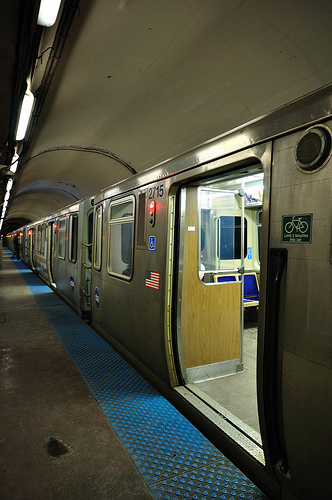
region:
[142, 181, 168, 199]
numbers on the side of the train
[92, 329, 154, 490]
blue metal divider of the boarding rail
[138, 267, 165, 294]
american flag on the side of the train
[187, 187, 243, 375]
wood paneled divider on the inside of the train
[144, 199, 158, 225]
boarding lights next to the door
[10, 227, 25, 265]
a man stepping onto the train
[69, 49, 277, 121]
white concrete cieling of the subway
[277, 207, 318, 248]
green and white sign showing a bicycle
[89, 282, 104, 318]
blue logo of the train company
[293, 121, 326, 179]
speaker on the side of the train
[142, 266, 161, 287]
an american flag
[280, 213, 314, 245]
green and white sign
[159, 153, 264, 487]
subway doors that are open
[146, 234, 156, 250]
white and blue handicap sign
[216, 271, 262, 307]
two blue seats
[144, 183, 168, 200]
number 2715 on side of subway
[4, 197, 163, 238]
red lights lit up along subway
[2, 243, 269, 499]
bumpy blue painted stripe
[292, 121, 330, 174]
a round speaker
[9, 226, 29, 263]
a person getting on the subway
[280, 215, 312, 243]
bike sign on subway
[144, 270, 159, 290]
US flag on subway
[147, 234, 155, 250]
Handicap stick on subway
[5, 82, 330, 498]
silver colored subway train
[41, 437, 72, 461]
small puddle on ground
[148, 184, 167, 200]
black subway train number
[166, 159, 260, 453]
open door on subway train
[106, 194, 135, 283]
window on subway train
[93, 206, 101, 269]
window on subway train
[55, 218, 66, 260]
window on subway train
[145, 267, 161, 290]
american flag sticker on the subway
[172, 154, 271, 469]
door entrance to the subway train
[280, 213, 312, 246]
bicycle sign on the side of the train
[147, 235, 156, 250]
handicapped sign on the side of the train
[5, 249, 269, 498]
blue textured stepping surface next to the subway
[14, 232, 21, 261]
man entering the subway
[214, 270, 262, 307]
blue seat on the subway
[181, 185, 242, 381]
wood wall partition inside the subway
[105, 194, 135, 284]
passenger window on the subway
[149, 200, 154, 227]
red lit light on the side of the train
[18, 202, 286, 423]
train doors are open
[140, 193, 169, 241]
red light on the wall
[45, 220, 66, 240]
red light on the wall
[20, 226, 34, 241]
red light on the wall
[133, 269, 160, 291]
American flag beside the door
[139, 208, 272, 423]
train door is open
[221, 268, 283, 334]
the seat is blue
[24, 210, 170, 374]
the train is silver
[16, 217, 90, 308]
the train is silver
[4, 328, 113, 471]
the floor is rusty